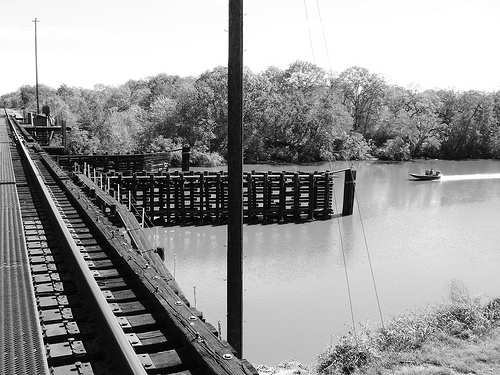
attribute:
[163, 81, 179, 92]
leaf — green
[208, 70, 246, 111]
leaf — green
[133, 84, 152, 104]
leaf — green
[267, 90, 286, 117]
leaf — green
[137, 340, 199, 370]
board — wooden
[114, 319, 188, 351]
board — wooden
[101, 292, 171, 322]
board — wooden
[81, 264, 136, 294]
board — wooden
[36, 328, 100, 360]
board — wooden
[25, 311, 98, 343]
board — wooden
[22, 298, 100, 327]
board — wooden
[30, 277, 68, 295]
board — wooden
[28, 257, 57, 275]
board — wooden